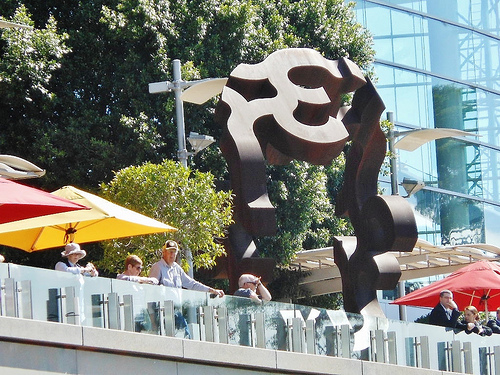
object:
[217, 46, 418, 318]
sculpture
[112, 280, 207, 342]
panel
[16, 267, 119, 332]
panel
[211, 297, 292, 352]
panel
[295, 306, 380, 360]
panel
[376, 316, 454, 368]
panel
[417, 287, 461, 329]
man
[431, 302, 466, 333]
suit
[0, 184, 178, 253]
umbrella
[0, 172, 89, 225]
umbrella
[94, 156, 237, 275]
tree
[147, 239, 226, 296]
man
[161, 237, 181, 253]
ball cap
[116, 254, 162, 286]
woman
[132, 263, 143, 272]
sunglasses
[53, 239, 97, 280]
woman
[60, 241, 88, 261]
sun hat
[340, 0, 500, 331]
building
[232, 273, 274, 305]
man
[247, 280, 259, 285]
sunglasses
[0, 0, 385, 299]
trees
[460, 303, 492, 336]
person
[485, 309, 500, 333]
person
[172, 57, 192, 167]
light pole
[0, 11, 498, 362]
plaza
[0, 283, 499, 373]
street